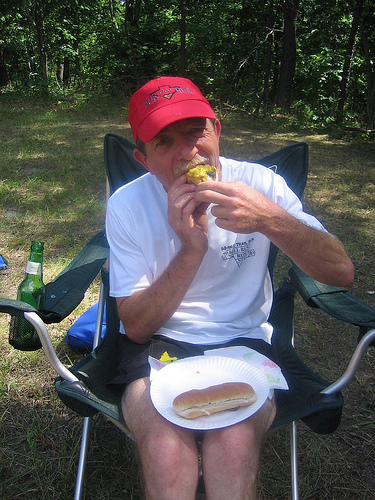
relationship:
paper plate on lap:
[148, 355, 270, 432] [112, 332, 278, 432]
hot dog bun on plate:
[169, 381, 258, 415] [148, 355, 270, 432]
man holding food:
[103, 75, 353, 500] [183, 164, 218, 188]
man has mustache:
[103, 75, 353, 500] [171, 156, 209, 171]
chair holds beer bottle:
[3, 135, 374, 439] [13, 240, 49, 351]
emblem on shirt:
[219, 236, 261, 268] [100, 157, 320, 350]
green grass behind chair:
[12, 124, 102, 209] [3, 135, 374, 439]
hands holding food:
[165, 180, 262, 244] [183, 164, 218, 188]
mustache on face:
[171, 156, 209, 171] [132, 117, 225, 190]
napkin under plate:
[212, 346, 285, 388] [148, 355, 270, 432]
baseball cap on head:
[123, 75, 216, 138] [127, 76, 224, 189]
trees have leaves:
[256, 4, 372, 123] [222, 23, 279, 94]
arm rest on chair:
[286, 286, 374, 347] [3, 135, 374, 439]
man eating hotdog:
[103, 75, 353, 500] [169, 381, 258, 415]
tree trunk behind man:
[277, 1, 298, 111] [103, 75, 353, 500]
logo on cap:
[136, 84, 192, 106] [123, 75, 216, 138]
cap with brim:
[123, 75, 216, 138] [130, 106, 220, 140]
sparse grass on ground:
[6, 391, 67, 466] [8, 106, 100, 232]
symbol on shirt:
[219, 236, 261, 268] [100, 157, 320, 350]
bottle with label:
[13, 240, 49, 351] [22, 258, 46, 280]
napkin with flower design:
[212, 346, 285, 388] [256, 356, 278, 371]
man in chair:
[103, 75, 353, 500] [3, 135, 374, 439]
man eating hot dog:
[103, 75, 353, 500] [169, 381, 258, 415]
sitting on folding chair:
[100, 323, 313, 425] [3, 135, 374, 439]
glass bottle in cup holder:
[13, 240, 49, 351] [2, 298, 57, 323]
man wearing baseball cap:
[103, 75, 353, 500] [123, 75, 216, 138]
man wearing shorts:
[103, 75, 353, 500] [112, 327, 292, 402]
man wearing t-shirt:
[103, 75, 353, 500] [100, 157, 320, 350]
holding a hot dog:
[165, 180, 262, 244] [183, 164, 218, 188]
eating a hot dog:
[173, 158, 220, 194] [183, 164, 218, 188]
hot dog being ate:
[183, 164, 218, 188] [173, 158, 220, 194]